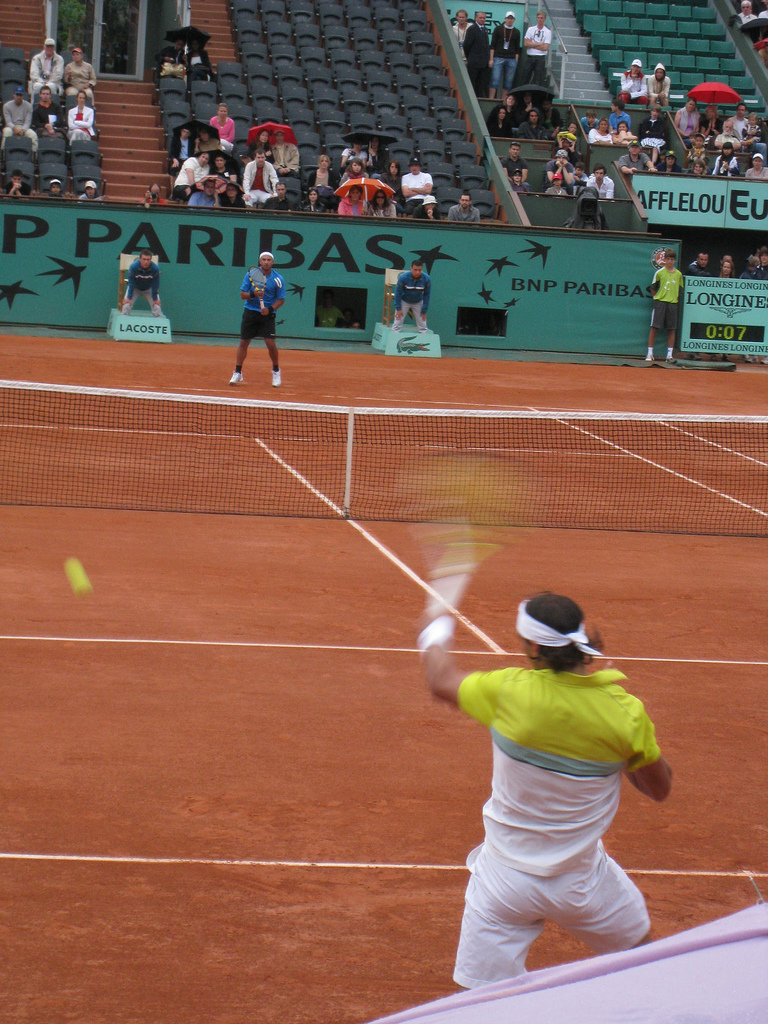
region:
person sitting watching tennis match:
[0, 84, 43, 154]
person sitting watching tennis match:
[29, 34, 68, 108]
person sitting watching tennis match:
[60, 41, 99, 106]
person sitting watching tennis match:
[25, 83, 64, 137]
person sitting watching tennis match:
[67, 85, 97, 142]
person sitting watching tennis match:
[240, 144, 290, 207]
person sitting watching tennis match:
[299, 151, 342, 216]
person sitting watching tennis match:
[396, 153, 442, 218]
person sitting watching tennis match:
[442, 184, 479, 221]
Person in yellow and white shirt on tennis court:
[504, 667, 655, 840]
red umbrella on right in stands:
[683, 70, 747, 100]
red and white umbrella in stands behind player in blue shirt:
[337, 171, 390, 190]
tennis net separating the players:
[0, 394, 332, 493]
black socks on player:
[222, 358, 249, 368]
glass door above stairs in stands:
[89, 0, 155, 69]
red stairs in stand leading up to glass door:
[102, 81, 143, 189]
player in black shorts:
[231, 305, 286, 347]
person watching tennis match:
[613, 54, 654, 111]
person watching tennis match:
[646, 58, 674, 117]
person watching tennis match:
[582, 161, 617, 200]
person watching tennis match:
[539, 141, 578, 195]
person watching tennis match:
[497, 137, 534, 189]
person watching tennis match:
[670, 93, 702, 143]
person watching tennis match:
[721, 97, 762, 143]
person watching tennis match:
[710, 139, 738, 176]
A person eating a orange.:
[508, 797, 586, 893]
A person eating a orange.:
[379, 775, 428, 941]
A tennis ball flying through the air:
[71, 566, 81, 585]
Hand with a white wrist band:
[424, 630, 448, 638]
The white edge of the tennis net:
[282, 405, 322, 409]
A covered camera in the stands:
[578, 197, 595, 213]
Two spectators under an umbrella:
[338, 181, 395, 217]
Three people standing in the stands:
[469, 8, 553, 71]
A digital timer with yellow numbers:
[706, 324, 747, 340]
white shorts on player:
[410, 822, 697, 998]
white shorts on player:
[433, 821, 663, 986]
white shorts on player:
[433, 836, 663, 991]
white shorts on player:
[428, 823, 666, 999]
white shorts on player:
[435, 818, 654, 1000]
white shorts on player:
[436, 827, 652, 994]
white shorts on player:
[425, 834, 657, 1002]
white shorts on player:
[426, 833, 649, 996]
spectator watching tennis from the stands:
[444, 190, 481, 221]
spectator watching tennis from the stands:
[367, 186, 398, 215]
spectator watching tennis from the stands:
[340, 181, 367, 215]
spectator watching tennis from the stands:
[298, 181, 324, 215]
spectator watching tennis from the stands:
[395, 155, 433, 204]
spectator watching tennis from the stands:
[0, 79, 40, 154]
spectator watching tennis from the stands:
[616, 57, 650, 106]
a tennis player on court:
[227, 251, 286, 384]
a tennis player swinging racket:
[388, 444, 669, 998]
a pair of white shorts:
[449, 845, 653, 986]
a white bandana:
[517, 596, 603, 657]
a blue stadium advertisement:
[5, 197, 680, 356]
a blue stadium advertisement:
[629, 172, 766, 229]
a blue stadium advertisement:
[676, 273, 765, 355]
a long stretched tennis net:
[2, 377, 766, 530]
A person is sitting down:
[401, 153, 433, 204]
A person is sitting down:
[307, 153, 338, 178]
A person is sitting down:
[295, 188, 323, 208]